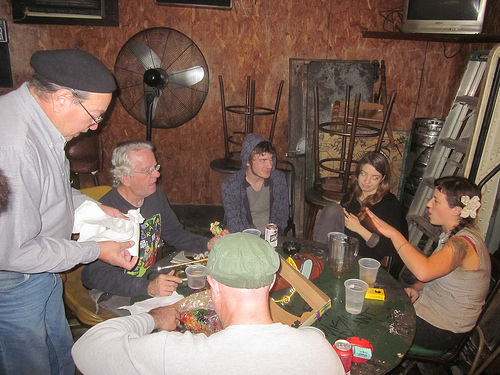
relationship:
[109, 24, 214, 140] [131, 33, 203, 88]
fan with blades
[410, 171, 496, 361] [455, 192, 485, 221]
woman with flower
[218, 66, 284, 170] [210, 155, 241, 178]
stool on table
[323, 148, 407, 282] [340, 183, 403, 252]
woman wearing shirt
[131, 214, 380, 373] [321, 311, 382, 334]
table with writing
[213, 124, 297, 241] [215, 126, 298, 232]
man wearing jacket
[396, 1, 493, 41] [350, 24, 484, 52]
tv on shelf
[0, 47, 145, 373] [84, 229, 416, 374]
man sitting at table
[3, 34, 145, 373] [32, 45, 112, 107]
man wearing beret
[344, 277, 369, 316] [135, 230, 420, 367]
cups on table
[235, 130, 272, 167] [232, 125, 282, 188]
hood on head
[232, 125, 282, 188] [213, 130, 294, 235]
head of man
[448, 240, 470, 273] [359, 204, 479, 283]
tattoo on arm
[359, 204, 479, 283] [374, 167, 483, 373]
arm of woman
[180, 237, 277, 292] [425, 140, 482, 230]
hat on head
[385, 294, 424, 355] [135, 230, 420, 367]
edge of table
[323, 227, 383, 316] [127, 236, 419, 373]
cups on table